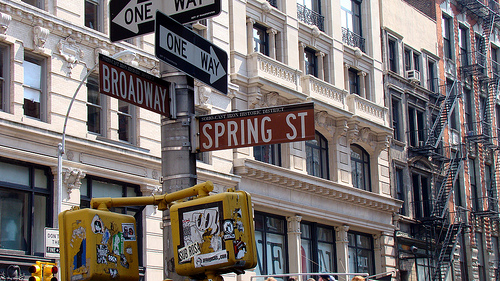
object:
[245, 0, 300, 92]
balcony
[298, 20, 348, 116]
balcony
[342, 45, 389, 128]
balcony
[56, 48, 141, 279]
light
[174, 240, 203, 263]
sticker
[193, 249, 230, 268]
sticker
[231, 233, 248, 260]
sticker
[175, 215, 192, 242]
sticker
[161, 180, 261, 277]
sign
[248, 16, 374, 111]
windows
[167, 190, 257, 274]
light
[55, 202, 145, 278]
light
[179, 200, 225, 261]
sticker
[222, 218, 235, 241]
sticker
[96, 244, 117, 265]
sticker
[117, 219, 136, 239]
sticker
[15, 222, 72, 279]
stoplight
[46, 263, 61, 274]
red light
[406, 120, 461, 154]
ground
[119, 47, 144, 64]
lights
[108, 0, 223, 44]
sign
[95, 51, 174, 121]
sign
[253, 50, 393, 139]
balcony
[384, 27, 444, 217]
stack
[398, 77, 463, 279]
fire-escape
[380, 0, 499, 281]
building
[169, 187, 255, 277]
stickers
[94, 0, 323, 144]
signs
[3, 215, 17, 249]
person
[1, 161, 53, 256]
window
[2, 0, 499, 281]
building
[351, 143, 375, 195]
window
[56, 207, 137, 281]
stickers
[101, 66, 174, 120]
white letters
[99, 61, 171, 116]
red background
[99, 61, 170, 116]
word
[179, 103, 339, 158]
sign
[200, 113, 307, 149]
white lettering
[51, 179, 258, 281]
street lights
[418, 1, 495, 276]
stairs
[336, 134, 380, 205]
window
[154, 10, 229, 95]
sign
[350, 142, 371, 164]
arch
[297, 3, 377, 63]
planters balcony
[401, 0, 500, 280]
fire escape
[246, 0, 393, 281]
building